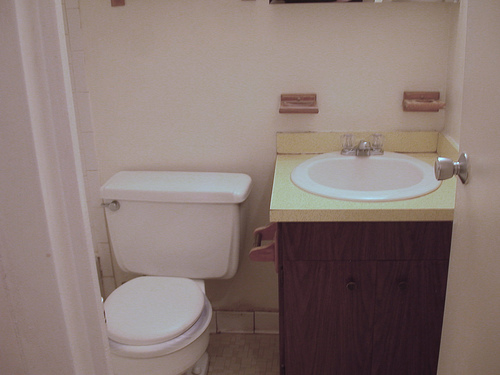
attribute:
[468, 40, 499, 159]
door — white, opened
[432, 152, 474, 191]
knob — silver, brown, chrome, steel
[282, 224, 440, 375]
cabinet — brown, wooden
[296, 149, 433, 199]
sink — white, circle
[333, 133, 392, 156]
faucet — silver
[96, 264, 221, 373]
toliet — white, cleaned, ceramic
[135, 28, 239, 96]
wall — white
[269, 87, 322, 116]
soap holder — brown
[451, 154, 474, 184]
handle — silver, chrome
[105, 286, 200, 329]
lid — closed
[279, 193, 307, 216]
counter — small, yellow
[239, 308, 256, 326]
tile — white, beige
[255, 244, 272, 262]
holder — pink, brown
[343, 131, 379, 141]
handles — clear, plastic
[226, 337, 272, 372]
floor — tile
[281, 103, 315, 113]
tray — wooden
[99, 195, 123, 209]
flush handle — silver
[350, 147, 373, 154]
fixture — chrome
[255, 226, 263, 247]
dispenser — wooden